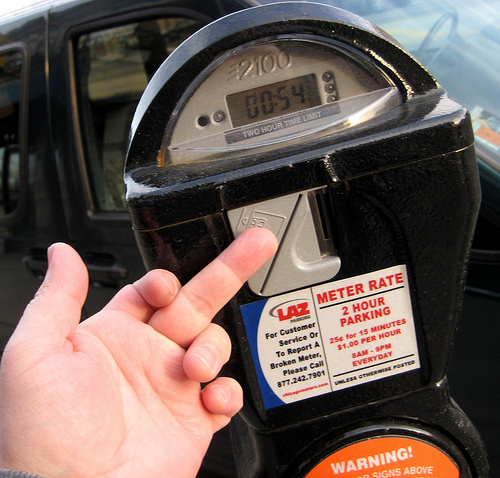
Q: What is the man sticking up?
A: Middle finger.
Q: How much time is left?
A: 54 minutes.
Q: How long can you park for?
A: 2 hours.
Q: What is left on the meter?
A: 54 minutes.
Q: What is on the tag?
A: Red, white, blue letters.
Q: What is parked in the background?
A: A vehicle.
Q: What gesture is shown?
A: Middle finger.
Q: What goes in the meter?
A: Money.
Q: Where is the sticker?
A: On the meter.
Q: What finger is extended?
A: Middle finger.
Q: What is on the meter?
A: Tag.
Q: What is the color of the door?
A: Black.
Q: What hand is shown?
A: Left hand.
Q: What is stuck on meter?
A: A tag.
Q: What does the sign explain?
A: The rate.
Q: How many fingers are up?
A: One.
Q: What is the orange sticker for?
A: Warning.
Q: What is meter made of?
A: Metal.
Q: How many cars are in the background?
A: One.